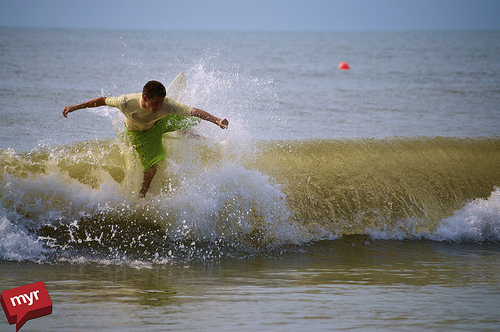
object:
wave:
[29, 135, 498, 237]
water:
[4, 26, 497, 330]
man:
[62, 80, 230, 199]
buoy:
[338, 61, 351, 71]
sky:
[3, 1, 496, 39]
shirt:
[105, 93, 194, 131]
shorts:
[126, 114, 200, 173]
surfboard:
[164, 69, 188, 98]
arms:
[74, 93, 217, 125]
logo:
[0, 278, 54, 331]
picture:
[0, 1, 499, 332]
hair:
[142, 79, 166, 100]